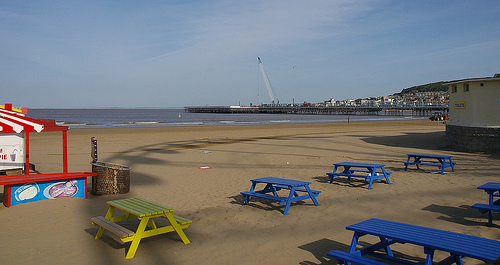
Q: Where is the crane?
A: Background.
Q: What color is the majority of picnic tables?
A: Blue.